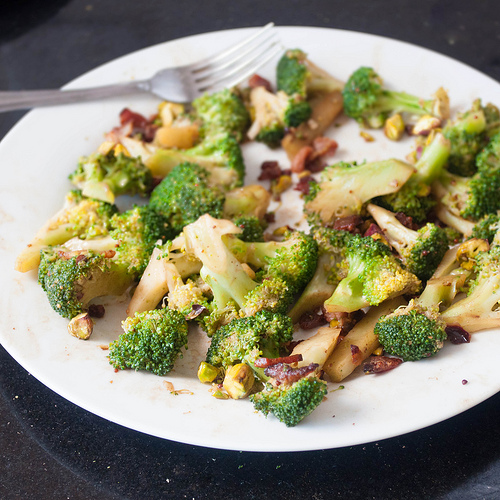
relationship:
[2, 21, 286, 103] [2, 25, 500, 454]
fork on plate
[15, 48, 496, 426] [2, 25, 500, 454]
broccoli on plate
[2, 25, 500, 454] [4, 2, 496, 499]
plate on top of table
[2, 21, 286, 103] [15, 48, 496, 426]
fork next to broccoli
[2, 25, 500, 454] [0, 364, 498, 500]
plate has reflection